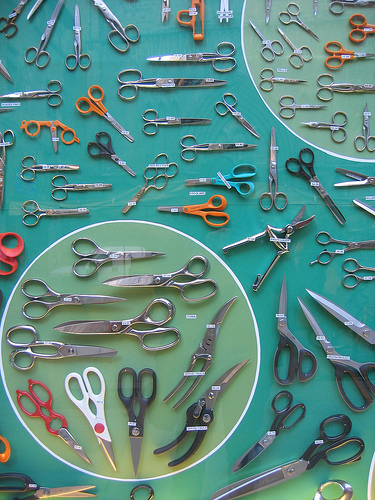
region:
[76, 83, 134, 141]
Scissors with orange handle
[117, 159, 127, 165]
A tag on the scissors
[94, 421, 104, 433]
Red circle on handle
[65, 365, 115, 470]
Scissors with white handle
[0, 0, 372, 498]
The mat is blue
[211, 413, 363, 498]
Scissors with long blades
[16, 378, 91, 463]
Scissors with oddly shaped handle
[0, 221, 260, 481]
Circle is green and white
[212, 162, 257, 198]
The handle is blue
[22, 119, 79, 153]
Weird looking pair of scissors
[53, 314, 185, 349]
Pair of metal sizzors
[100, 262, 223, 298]
Pair of metal sizzors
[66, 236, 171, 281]
Pair of metal sizzors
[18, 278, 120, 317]
Pair of metal sizzors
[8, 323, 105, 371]
Pair of metal sizzors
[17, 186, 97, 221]
Pair of metal sizzors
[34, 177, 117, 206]
Pair of metal sizzors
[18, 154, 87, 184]
Pair of metal sizzors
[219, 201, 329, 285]
Pair of metal sizzors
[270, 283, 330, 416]
Pair of metal sizzors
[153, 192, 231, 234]
Safety scissors with an orange handle.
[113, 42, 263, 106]
All metal scissors.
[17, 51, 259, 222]
A variety of scissors with different handles.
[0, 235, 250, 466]
A group of various scissors.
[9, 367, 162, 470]
Three pairs of scissors with different colored handles.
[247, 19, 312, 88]
Set of three small scissors.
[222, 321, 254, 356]
The green painted surface of a table.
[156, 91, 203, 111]
The teal colored surface of the table.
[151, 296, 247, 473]
Scissors with a curved blade.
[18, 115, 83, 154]
A small pair of foldable scissors.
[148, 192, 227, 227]
Orange scissors next to blue scissors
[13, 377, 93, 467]
Red scissors next to white scissors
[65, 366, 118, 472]
White scissors next to black scissors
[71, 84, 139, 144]
Orange scissors next to black scissors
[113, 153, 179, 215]
Double handle scissors in front of blue scissors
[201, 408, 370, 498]
Large black scissors next to small black scissors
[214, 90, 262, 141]
Small silver scissors in front of silver scissors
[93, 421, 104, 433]
Red circular dot on white scissors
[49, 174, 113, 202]
Small silver scissors next to silver scissors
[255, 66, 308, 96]
Small silver scissors next to small silver scissors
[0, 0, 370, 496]
Scissors on a green surface.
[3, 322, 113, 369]
Metal scissors with metal handles.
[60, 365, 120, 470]
Scissors with white handles.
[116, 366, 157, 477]
Scissors with black handles.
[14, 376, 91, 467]
Scissors with red handles.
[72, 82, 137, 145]
Scissors with orange handles.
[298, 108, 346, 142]
Needle nose scissors.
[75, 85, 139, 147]
Scissors with rounded blades.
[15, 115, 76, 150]
Scissors with folding handles.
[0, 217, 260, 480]
Scissors lying in a green circle.